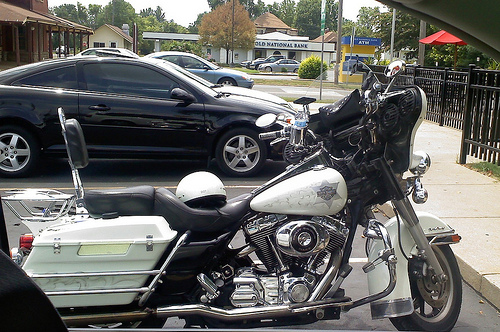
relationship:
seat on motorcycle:
[57, 113, 254, 228] [10, 62, 471, 325]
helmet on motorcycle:
[170, 168, 230, 213] [10, 62, 471, 325]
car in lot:
[2, 48, 291, 176] [2, 42, 492, 326]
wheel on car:
[214, 124, 271, 179] [2, 48, 291, 176]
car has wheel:
[2, 48, 291, 176] [214, 124, 271, 179]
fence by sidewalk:
[366, 59, 499, 168] [409, 84, 499, 300]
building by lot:
[0, 1, 55, 66] [2, 42, 492, 326]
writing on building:
[253, 37, 317, 51] [145, 20, 335, 77]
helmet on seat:
[170, 168, 230, 213] [57, 113, 254, 228]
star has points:
[313, 177, 344, 209] [311, 177, 348, 214]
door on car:
[78, 60, 204, 163] [2, 48, 291, 176]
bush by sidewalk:
[297, 55, 329, 81] [255, 71, 302, 83]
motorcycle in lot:
[10, 62, 471, 325] [2, 42, 492, 326]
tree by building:
[203, 1, 255, 65] [145, 20, 335, 77]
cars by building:
[245, 53, 305, 73] [0, 1, 55, 66]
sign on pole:
[316, 1, 331, 40] [318, 30, 327, 107]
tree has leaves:
[203, 1, 255, 65] [197, 3, 258, 50]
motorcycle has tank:
[10, 62, 471, 325] [251, 164, 347, 215]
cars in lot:
[245, 53, 305, 73] [2, 42, 492, 326]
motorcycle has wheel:
[10, 62, 471, 325] [384, 227, 465, 331]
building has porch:
[0, 1, 55, 66] [2, 23, 92, 71]